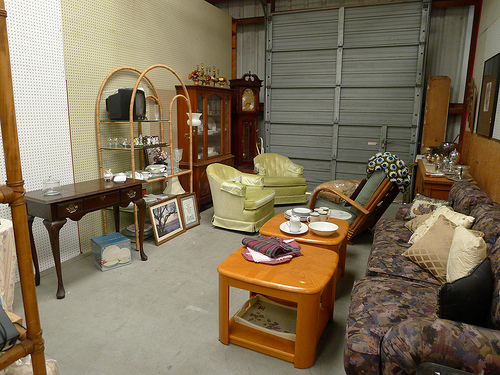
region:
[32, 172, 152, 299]
Dark wood table against the wall.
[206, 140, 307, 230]
Green chairs in the back.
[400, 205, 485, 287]
Tan and brown pillows on the couch.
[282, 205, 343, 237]
White dishes on the table.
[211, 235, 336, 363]
Light brown end table.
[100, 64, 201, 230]
Wood and glass shelving unit.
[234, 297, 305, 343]
White and green serving tray.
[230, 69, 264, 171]
Grandfather clock behind chairs.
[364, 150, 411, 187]
Crocheted blue,white, and brown afghan.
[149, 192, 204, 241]
Pictures on the floor.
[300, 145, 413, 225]
a recliner in the room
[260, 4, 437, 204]
a metal door in the room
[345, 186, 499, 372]
a long sofa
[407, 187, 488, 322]
pillows on the sofa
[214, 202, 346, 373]
tables in front of the sofa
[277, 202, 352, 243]
dishes on the table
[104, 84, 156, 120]
a TV on top of the shelf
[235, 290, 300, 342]
a tray under the table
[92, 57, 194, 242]
a wicker shelf across from the sofa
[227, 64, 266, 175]
a clock in the corner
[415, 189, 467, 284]
pillows on the couch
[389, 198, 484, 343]
pillows on the couch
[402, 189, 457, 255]
pillows on the couch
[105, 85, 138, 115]
a small black tv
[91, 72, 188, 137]
a small black tv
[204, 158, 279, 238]
upholstered chair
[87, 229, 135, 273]
box of dishes sitting on floor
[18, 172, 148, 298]
cherry wood Queen Anne style desk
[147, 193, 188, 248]
framed artwork sitting on floor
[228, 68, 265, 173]
dark wood grandfather clock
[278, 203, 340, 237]
dishes sitting on table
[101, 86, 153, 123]
small television sitting on bookcase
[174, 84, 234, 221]
light colored china cabinet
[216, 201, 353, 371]
pair of light tables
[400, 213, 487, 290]
pillows sitting on sofa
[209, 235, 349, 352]
Small wooden table in room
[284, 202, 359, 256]
Small wooden table in room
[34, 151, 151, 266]
Small wooden table in room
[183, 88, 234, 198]
Wooden china cabinet in room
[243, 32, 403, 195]
Large metal garage door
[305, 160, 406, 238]
Antique reclining chair in room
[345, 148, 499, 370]
Sofa with pillows on right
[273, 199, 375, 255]
White bowls on table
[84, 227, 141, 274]
Blue box under table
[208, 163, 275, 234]
Yellow leather recliner